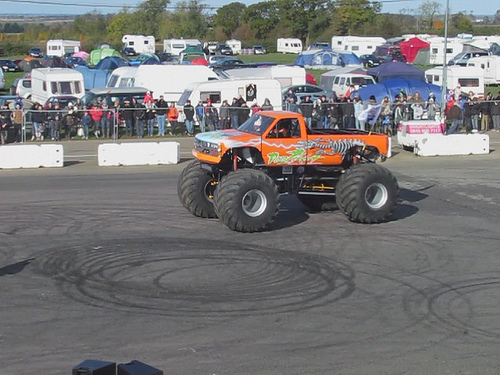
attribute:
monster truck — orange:
[179, 108, 405, 235]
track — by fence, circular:
[41, 235, 353, 314]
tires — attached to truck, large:
[217, 168, 400, 237]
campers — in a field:
[28, 31, 256, 54]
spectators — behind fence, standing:
[1, 104, 239, 137]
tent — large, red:
[400, 31, 428, 60]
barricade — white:
[97, 141, 180, 166]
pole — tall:
[444, 0, 448, 136]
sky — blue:
[2, 1, 133, 24]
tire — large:
[216, 172, 275, 232]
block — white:
[0, 143, 65, 169]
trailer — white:
[429, 62, 485, 93]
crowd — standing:
[299, 94, 492, 132]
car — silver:
[284, 83, 338, 100]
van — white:
[175, 81, 283, 119]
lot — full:
[1, 31, 495, 66]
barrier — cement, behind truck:
[416, 132, 491, 156]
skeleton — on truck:
[307, 139, 360, 155]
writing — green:
[263, 152, 321, 165]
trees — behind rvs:
[37, 2, 449, 37]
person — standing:
[157, 95, 170, 132]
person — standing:
[65, 100, 77, 134]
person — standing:
[482, 94, 492, 132]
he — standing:
[182, 99, 195, 132]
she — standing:
[90, 106, 101, 134]